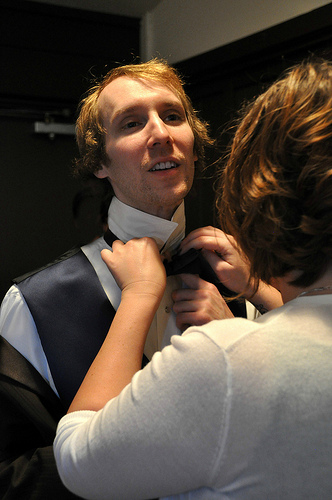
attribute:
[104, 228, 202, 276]
tie — black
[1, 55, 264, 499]
man — white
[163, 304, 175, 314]
button — round, brown, small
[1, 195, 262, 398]
shirt — white, formal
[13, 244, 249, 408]
vest — shiny, black, formal, satin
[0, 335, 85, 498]
jacket — hanging, black, pin striped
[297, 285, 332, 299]
necklace — silver, thin, metal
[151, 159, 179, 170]
teeth — white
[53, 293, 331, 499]
shirt — thin, white, cotton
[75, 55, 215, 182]
hair — blonde, long, brown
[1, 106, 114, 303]
door — dark colored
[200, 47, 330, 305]
hair — brown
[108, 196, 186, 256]
collar — white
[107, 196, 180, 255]
right collar — pointy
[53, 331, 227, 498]
left sleeve — quarter length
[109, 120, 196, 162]
cheekbones — prominent